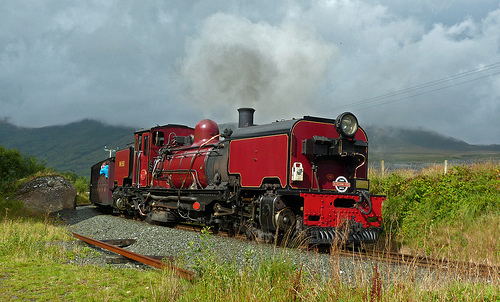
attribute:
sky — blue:
[1, 0, 498, 152]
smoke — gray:
[174, 15, 289, 115]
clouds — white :
[324, 7, 499, 87]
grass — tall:
[0, 221, 171, 300]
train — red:
[72, 142, 389, 242]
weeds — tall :
[200, 232, 499, 299]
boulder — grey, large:
[13, 165, 79, 225]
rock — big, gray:
[6, 168, 84, 216]